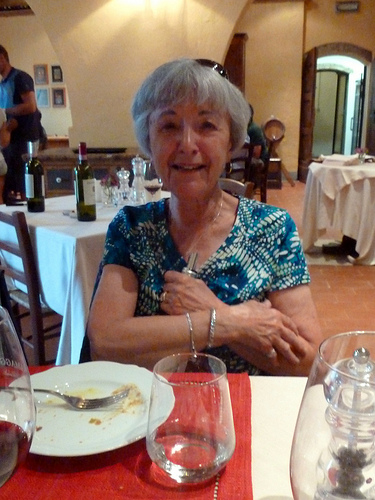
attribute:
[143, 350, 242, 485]
glass — clear, empty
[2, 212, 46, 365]
chair —  Wood 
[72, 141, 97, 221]
bottle —  for wine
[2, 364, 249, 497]
placemat — cloth, red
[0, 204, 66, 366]
chair —  wooden,  empty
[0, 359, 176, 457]
plate —  White, white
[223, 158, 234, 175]
earrings — hoops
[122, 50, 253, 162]
hair — grey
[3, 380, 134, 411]
fork — silver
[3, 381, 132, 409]
fork —  metal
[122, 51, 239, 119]
gray hair —    Gray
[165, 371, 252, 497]
place mat — red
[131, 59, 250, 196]
head —  woman's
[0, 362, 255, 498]
place mat —  red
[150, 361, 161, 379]
edge —  cup's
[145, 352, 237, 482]
glass —  empty,  small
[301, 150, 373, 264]
table cloths —  white, for table,  long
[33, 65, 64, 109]
pictures — several